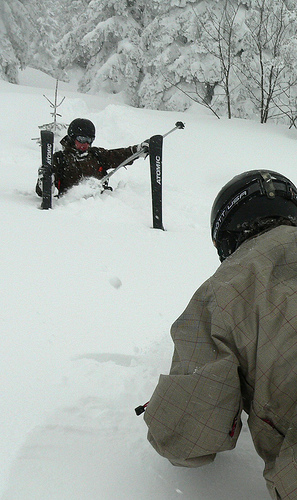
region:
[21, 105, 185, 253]
a skier in the snow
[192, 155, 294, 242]
black helmet on head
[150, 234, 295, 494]
a brown jacket with red lines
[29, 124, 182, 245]
black skis with white writing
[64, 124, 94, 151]
goggles worn on face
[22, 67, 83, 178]
a small tree behind skier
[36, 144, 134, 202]
black jacket with red spots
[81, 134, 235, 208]
one ski pole in hand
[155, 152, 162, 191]
white writing on ski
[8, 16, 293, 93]
snow covered trees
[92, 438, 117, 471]
part fo a snow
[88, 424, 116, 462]
part of a snow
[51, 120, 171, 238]
A person skiing that fell in the snow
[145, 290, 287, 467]
This person is wearing a tan plaid coat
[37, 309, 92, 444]
The snow may be fresh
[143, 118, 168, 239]
A black ski sticking from the snow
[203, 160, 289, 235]
This person is wearing a black helemt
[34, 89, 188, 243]
The person is stuck in the snow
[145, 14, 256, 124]
The trees are covered in snow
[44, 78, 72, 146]
A very small evergreen tree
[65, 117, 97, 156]
The skier is wearing a helmet and ski goggle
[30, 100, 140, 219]
Skier looks to be sitting in the snow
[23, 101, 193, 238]
person on skiis fallen in the snow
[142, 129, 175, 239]
left ski in the snow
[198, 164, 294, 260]
black helmet on person in the snow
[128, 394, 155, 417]
black tag on plaid jacket in the snow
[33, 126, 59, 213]
right ski in the snow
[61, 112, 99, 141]
black helmet on person in the snow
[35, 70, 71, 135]
small pine tree in the snow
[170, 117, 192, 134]
end of ski pole in the snow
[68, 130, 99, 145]
snow googles on a person in the snow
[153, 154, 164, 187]
words on a black ski in the snow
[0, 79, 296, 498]
a field of snow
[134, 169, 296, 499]
a man in the snow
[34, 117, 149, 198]
a skier who fell into the snow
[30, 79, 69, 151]
a small pine tree behind the skier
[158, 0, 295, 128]
a group of leafless trees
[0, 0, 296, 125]
a group of pine trees in the background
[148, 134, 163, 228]
a ski buried in the snow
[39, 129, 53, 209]
a ski in the snow on the left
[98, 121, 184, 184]
a ski pole held by the skier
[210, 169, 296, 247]
a helmet on the nearest man